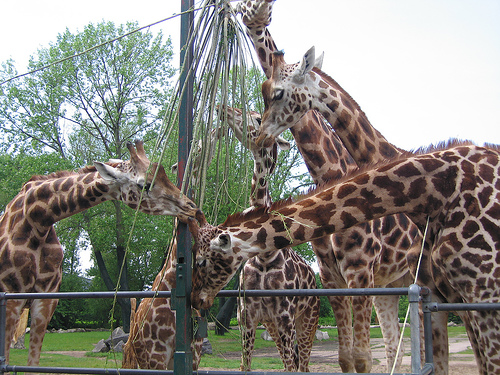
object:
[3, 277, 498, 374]
enclosure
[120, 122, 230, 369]
giraffe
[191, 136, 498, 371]
giraffe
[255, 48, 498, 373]
giraffe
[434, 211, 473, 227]
spots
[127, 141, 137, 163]
horn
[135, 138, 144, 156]
horn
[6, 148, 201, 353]
giraffe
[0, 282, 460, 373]
fence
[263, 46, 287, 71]
horn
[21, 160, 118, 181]
mane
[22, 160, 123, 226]
neck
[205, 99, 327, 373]
giraffe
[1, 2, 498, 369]
enclosure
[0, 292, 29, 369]
leg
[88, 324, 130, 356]
rocks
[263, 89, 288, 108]
eye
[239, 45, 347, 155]
head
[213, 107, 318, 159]
mouth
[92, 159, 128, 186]
ear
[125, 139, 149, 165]
short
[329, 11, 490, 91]
overcast sky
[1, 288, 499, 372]
enclosure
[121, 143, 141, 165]
horns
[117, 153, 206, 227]
head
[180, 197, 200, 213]
nose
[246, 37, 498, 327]
giraffe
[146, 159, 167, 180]
bump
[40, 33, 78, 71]
leaves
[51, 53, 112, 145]
branches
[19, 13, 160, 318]
tree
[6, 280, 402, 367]
bars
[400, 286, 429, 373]
pole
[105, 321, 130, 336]
top